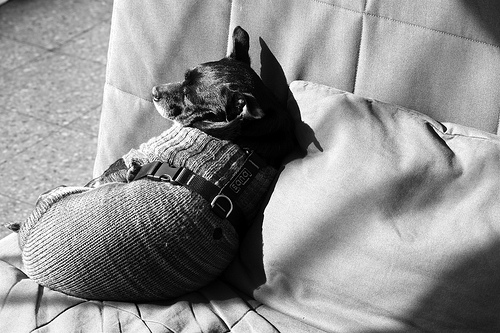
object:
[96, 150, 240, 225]
harness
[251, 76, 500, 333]
pillow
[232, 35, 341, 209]
shadow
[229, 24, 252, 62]
ear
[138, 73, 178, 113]
muzzle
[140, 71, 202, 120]
nose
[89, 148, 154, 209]
paw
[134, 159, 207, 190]
harness clasp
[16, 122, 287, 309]
sweater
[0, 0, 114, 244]
floor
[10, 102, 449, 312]
cover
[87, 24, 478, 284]
bed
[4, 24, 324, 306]
dog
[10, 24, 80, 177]
tiles